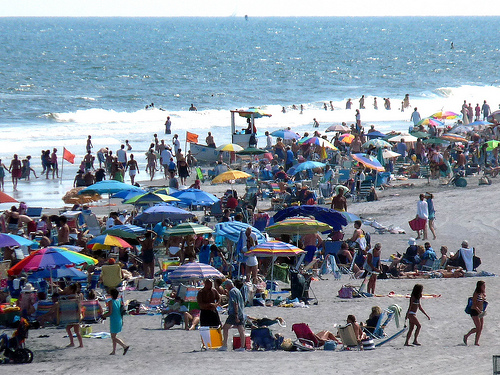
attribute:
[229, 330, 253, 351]
cooler — red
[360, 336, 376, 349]
bag — white, blue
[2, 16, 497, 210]
water — choppy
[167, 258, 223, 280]
umbrella — striped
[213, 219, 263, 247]
umbrella — striped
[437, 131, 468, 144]
umbrella — striped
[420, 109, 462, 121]
umbrella — striped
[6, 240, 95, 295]
umbrella — multi colored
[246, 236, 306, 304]
umbrella — striped, multi colored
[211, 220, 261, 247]
umbrella — multi colored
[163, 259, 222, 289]
umbrella — multi colored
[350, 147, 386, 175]
umbrella — multi colored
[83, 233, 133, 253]
umbrella — multi colored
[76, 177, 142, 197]
umbrella — blue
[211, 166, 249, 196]
umbrella — yellow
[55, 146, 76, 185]
flag — red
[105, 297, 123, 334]
dress — blue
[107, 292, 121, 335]
dress — sleeveless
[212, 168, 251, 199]
umbrella — large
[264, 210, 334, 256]
umbrella — large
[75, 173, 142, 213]
umbrella — large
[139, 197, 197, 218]
umbrella — large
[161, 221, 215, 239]
umbrella — large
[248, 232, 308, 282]
umbrella — large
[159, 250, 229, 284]
umbrella — large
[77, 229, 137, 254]
umbrella — large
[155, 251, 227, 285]
umbrella — purple, pink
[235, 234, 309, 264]
umbrella — blue, orange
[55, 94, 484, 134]
wave — white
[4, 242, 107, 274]
umbrella — multi colored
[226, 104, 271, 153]
life guard — distant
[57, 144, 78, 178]
flag — orange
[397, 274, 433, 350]
woman — walking away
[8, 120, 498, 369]
beach — large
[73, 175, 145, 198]
umbrella — large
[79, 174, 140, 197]
umbrella — large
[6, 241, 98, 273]
umbrella — large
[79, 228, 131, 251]
umbrella — large